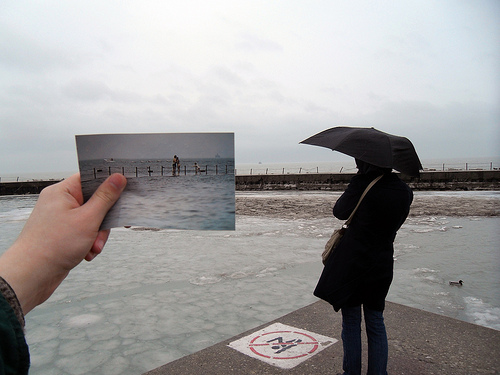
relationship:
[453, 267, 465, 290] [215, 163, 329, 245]
duck in water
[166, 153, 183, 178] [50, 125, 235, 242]
person in photo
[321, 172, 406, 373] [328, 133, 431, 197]
person holds umbrella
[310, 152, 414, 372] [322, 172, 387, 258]
person carries sling bag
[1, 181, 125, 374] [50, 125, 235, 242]
person holds photo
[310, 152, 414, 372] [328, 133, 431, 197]
person carries umbrella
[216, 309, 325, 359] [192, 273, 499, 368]
sign on ground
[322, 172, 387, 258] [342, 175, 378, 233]
sling bag has strap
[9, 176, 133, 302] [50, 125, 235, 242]
hand holds photo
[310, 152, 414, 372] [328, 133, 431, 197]
person holds umbrella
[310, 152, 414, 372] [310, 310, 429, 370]
person wears jeans